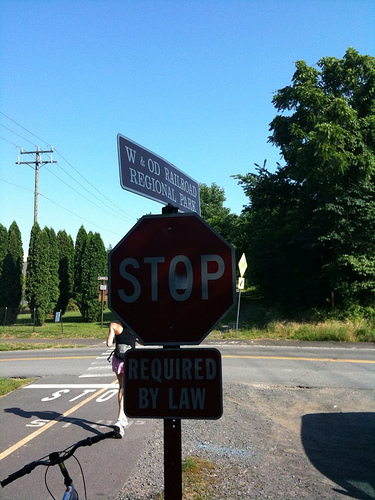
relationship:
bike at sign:
[0, 429, 118, 498] [104, 130, 240, 443]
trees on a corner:
[0, 220, 108, 323] [0, 310, 105, 344]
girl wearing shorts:
[107, 315, 129, 438] [109, 350, 128, 377]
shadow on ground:
[8, 391, 147, 455] [31, 351, 361, 495]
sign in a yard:
[98, 133, 243, 412] [0, 295, 340, 343]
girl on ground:
[107, 315, 129, 438] [0, 348, 362, 497]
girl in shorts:
[107, 315, 129, 438] [106, 355, 132, 374]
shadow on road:
[296, 403, 373, 497] [0, 335, 373, 497]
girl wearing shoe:
[107, 315, 129, 438] [83, 389, 139, 442]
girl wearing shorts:
[107, 315, 129, 438] [97, 347, 159, 375]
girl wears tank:
[107, 315, 129, 438] [112, 320, 136, 347]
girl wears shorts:
[107, 315, 129, 438] [110, 353, 123, 373]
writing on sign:
[130, 353, 217, 409] [123, 346, 223, 420]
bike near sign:
[0, 429, 118, 498] [106, 131, 239, 499]